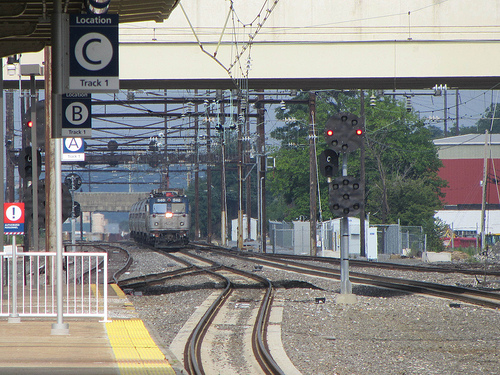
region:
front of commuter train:
[133, 194, 186, 251]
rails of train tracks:
[102, 246, 493, 373]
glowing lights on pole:
[321, 111, 363, 295]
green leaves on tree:
[268, 95, 436, 220]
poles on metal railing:
[3, 251, 109, 321]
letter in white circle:
[73, 30, 113, 70]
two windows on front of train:
[153, 200, 185, 214]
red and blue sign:
[1, 200, 25, 315]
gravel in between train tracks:
[136, 251, 491, 373]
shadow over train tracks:
[153, 274, 427, 296]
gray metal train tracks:
[144, 239, 498, 371]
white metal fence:
[0, 252, 111, 324]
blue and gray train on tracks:
[126, 192, 190, 248]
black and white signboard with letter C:
[67, 12, 118, 96]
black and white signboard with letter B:
[54, 89, 93, 138]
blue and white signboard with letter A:
[55, 133, 84, 160]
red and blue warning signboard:
[0, 196, 31, 233]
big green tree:
[274, 91, 443, 223]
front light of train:
[162, 210, 176, 222]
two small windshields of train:
[152, 199, 185, 216]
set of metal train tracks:
[170, 295, 285, 370]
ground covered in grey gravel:
[293, 307, 478, 367]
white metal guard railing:
[0, 247, 107, 315]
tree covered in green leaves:
[369, 102, 446, 218]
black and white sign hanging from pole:
[64, 12, 134, 92]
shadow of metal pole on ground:
[132, 265, 321, 301]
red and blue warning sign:
[0, 191, 30, 238]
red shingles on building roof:
[441, 157, 483, 207]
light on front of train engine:
[162, 210, 180, 222]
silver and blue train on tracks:
[109, 174, 204, 259]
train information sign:
[68, 15, 118, 92]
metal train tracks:
[160, 248, 280, 370]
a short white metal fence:
[1, 254, 110, 321]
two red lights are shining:
[321, 112, 365, 152]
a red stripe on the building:
[428, 160, 498, 204]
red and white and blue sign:
[2, 202, 25, 237]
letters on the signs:
[60, 16, 119, 160]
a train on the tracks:
[124, 190, 198, 252]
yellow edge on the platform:
[105, 317, 170, 374]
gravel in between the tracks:
[284, 293, 487, 369]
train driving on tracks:
[111, 183, 206, 260]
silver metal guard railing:
[0, 248, 118, 322]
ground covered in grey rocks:
[324, 311, 476, 373]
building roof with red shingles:
[431, 154, 498, 204]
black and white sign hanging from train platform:
[66, 11, 130, 98]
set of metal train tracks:
[183, 278, 288, 373]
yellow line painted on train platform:
[94, 312, 171, 374]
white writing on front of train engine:
[152, 194, 183, 204]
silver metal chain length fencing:
[261, 217, 303, 259]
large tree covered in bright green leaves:
[367, 103, 447, 225]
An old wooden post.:
[305, 92, 321, 253]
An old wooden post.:
[253, 95, 268, 252]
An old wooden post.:
[241, 101, 247, 248]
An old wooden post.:
[232, 92, 244, 252]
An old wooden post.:
[215, 90, 231, 245]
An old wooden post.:
[206, 92, 214, 246]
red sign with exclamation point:
[3, 200, 23, 230]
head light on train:
[163, 209, 174, 218]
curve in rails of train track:
[175, 270, 290, 365]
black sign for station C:
[68, 28, 120, 87]